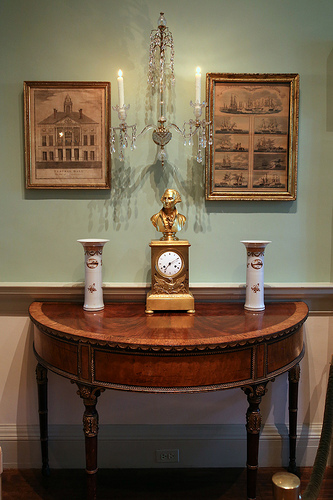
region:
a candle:
[190, 68, 210, 106]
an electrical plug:
[151, 448, 185, 464]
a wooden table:
[146, 314, 212, 345]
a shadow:
[4, 453, 62, 495]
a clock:
[156, 254, 184, 274]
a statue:
[151, 185, 189, 235]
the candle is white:
[111, 69, 129, 106]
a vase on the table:
[69, 233, 113, 307]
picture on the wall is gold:
[206, 72, 294, 197]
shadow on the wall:
[120, 172, 180, 187]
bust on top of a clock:
[148, 186, 188, 237]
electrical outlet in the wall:
[153, 445, 182, 465]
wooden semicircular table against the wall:
[20, 297, 305, 483]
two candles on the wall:
[104, 60, 217, 174]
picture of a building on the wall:
[16, 78, 113, 201]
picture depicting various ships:
[204, 69, 297, 206]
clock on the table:
[142, 237, 198, 318]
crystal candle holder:
[100, 12, 219, 176]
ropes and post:
[272, 357, 330, 498]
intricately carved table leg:
[61, 377, 115, 487]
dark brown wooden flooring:
[0, 468, 332, 497]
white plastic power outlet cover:
[154, 446, 180, 462]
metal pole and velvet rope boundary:
[271, 353, 331, 498]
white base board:
[0, 423, 332, 466]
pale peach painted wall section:
[0, 315, 332, 425]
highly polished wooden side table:
[26, 297, 310, 497]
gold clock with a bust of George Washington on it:
[143, 186, 196, 314]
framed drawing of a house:
[21, 78, 112, 191]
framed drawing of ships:
[203, 70, 300, 203]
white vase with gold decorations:
[239, 238, 271, 310]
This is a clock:
[139, 252, 231, 305]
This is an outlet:
[145, 430, 207, 487]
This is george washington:
[157, 201, 182, 221]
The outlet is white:
[157, 446, 181, 470]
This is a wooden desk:
[80, 328, 136, 384]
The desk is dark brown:
[100, 308, 161, 369]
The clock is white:
[167, 252, 177, 274]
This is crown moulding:
[148, 427, 190, 453]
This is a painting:
[218, 151, 251, 196]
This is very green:
[17, 407, 39, 470]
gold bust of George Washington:
[151, 190, 189, 238]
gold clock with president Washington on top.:
[145, 190, 193, 314]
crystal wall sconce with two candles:
[113, 22, 208, 169]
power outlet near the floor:
[156, 450, 178, 462]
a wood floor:
[3, 468, 331, 498]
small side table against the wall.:
[30, 303, 304, 495]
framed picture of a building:
[23, 81, 112, 192]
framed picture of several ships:
[205, 74, 293, 199]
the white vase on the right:
[239, 240, 270, 311]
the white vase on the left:
[78, 239, 107, 310]